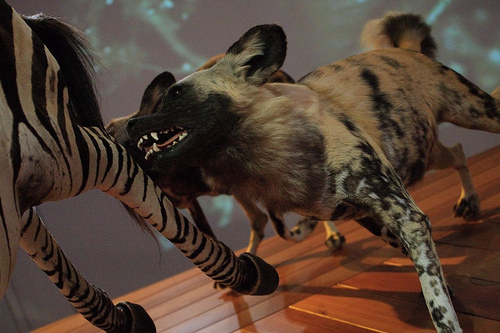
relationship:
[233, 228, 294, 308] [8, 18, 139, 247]
hoof of zebra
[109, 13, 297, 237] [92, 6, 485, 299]
mouth of hyena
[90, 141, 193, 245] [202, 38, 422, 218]
leg of hyena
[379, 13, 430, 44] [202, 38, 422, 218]
tail of hyena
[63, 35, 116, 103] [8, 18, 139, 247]
tail of zebra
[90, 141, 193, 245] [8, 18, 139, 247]
leg of zebra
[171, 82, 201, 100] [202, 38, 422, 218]
eye of hyena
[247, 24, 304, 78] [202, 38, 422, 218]
ear of hyena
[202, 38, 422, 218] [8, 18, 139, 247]
hyena and zebra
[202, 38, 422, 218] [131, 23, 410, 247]
hyena on display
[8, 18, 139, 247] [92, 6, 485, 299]
zebra on display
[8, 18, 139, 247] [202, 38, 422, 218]
zebra and hyena